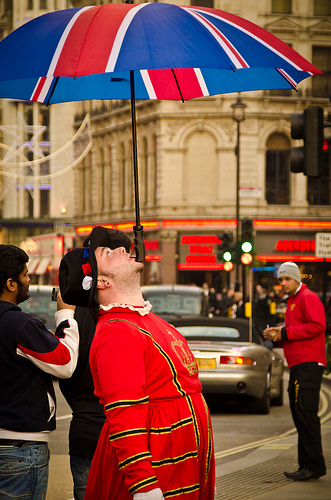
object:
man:
[58, 228, 215, 499]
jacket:
[84, 301, 219, 500]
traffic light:
[242, 218, 254, 267]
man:
[260, 260, 329, 481]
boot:
[291, 464, 328, 480]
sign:
[176, 234, 229, 271]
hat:
[57, 225, 109, 324]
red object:
[81, 262, 92, 275]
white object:
[81, 275, 94, 291]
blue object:
[83, 246, 89, 258]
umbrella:
[0, 3, 325, 265]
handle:
[130, 225, 146, 261]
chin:
[135, 262, 145, 275]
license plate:
[195, 356, 218, 371]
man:
[1, 243, 82, 499]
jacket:
[0, 299, 82, 443]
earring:
[106, 281, 110, 285]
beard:
[13, 274, 31, 304]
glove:
[129, 484, 168, 498]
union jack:
[0, 0, 322, 271]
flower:
[82, 248, 90, 260]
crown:
[167, 328, 200, 375]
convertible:
[164, 317, 287, 413]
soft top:
[166, 324, 240, 341]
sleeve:
[17, 310, 49, 371]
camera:
[50, 286, 64, 302]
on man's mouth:
[128, 253, 146, 269]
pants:
[284, 362, 327, 469]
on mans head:
[86, 245, 146, 309]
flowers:
[81, 274, 94, 292]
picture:
[54, 289, 57, 300]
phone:
[49, 288, 61, 302]